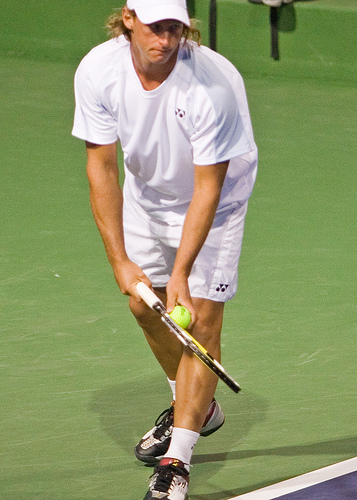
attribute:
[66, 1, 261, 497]
tennis player — preparing, serving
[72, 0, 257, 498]
unifirm — white, tennis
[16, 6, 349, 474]
court — green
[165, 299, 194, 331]
ball — resting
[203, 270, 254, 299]
logo — black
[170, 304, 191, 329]
ball — yellow, tennis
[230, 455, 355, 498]
boundary line — white 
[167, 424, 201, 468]
sock — white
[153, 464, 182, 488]
shoe lace — black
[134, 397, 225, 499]
shoes — tennis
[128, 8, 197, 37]
hat — plain , white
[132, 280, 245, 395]
racket — tennis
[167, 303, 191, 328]
ball — tennis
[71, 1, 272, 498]
player — tennis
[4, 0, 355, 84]
wall — green